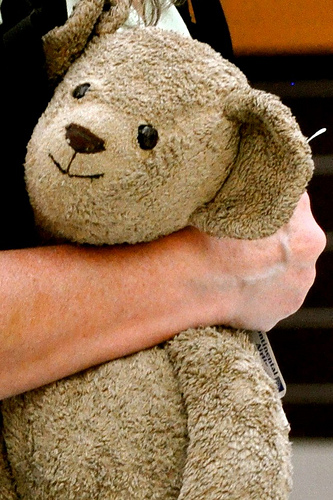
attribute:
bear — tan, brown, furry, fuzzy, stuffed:
[20, 3, 297, 498]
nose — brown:
[65, 117, 107, 163]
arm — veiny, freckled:
[1, 187, 324, 410]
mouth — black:
[45, 147, 113, 190]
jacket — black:
[2, 0, 249, 231]